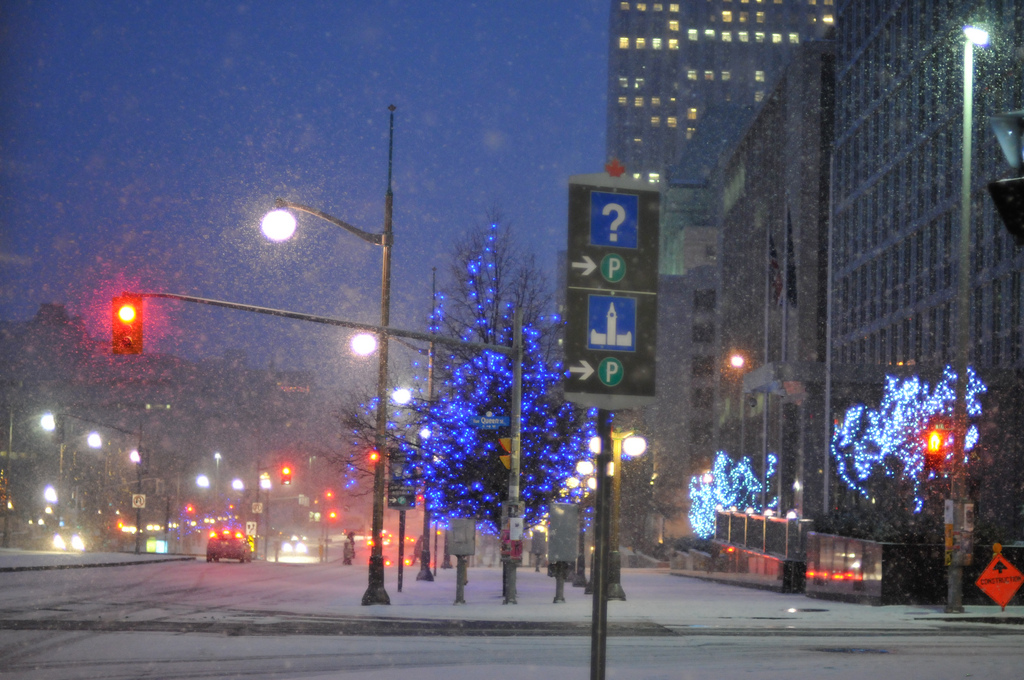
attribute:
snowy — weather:
[0, 8, 1009, 666]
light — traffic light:
[84, 274, 177, 344]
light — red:
[80, 267, 189, 385]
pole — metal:
[333, 98, 479, 614]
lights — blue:
[435, 349, 689, 593]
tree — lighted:
[836, 381, 979, 514]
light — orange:
[910, 411, 961, 472]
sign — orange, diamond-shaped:
[972, 543, 1021, 601]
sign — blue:
[577, 195, 645, 249]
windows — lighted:
[621, 8, 808, 47]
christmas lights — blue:
[384, 218, 597, 522]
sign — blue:
[473, 404, 506, 434]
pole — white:
[501, 307, 527, 586]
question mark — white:
[595, 200, 628, 246]